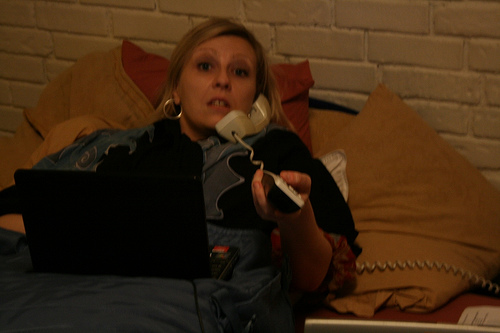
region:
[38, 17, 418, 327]
Woman laying down on bed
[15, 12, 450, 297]
Woman talking on phone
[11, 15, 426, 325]
Woman holding remote control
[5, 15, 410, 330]
Woman holding laptop while laying down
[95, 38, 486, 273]
Pillows behind woman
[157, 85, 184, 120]
Earing worn by a woman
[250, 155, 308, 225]
TV remote control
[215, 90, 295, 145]
Receiver for telephone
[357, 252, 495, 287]
Telephone cord laying on pillow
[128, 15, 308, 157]
Woman with blond hair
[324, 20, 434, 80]
the wall is made of bricks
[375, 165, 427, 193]
the pillowcase is golden brown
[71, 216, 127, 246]
the laptop is black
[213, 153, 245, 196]
the shirt is blue gray and black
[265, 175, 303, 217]
the bottom of the remote is black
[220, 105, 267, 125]
the phone is white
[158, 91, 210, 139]
the earring is gold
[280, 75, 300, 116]
the pillowcase is red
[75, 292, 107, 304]
the blanket is blue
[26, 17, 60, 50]
the brick are white in color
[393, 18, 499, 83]
The wall is brick.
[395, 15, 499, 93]
The brick is white.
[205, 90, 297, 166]
The person is using a phone.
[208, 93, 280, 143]
The phone is white.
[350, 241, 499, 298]
The phone has a cord.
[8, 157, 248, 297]
The person is holding a laptop.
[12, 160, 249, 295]
The laptop is black.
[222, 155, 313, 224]
The person is holding a remote.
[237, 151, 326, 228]
The remote is black and gray.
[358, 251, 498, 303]
The phone cord is white.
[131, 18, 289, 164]
lady talking on house phone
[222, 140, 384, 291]
left hand holding remote control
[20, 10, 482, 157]
wall made of brick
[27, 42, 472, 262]
mustard and rust bedding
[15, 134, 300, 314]
laptop resting on stomach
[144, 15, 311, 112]
lady has blonde hair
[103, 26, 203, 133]
silver hoop earring in right ear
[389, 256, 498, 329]
landline phone sitting on table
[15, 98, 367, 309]
jean shirt with black design on shoulders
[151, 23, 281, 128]
lady has on brown eye shadow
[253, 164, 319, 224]
hand holding remote control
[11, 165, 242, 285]
laptop computer on blanket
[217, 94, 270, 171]
telephone held between shoulder and chin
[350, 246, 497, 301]
spiral telephone cord laying across pillow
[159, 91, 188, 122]
large ear ring on right ear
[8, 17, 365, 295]
woman using telephone, mobile computer, and remote control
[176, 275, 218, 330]
power cord for laptop computer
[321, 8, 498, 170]
brick wall supporting pillows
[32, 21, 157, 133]
red and orange pillow on wall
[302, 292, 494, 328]
laptop computer on the bed